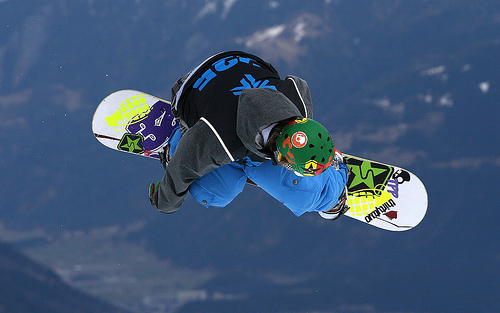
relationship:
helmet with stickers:
[269, 115, 340, 179] [303, 145, 304, 146]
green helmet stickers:
[316, 162, 318, 164] [303, 145, 304, 146]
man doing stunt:
[251, 121, 252, 122] [256, 117, 257, 118]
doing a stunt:
[223, 148, 224, 151] [256, 117, 257, 118]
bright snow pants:
[220, 184, 221, 185] [202, 185, 332, 204]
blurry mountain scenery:
[52, 22, 150, 170] [63, 41, 82, 196]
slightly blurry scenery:
[13, 58, 56, 302] [63, 41, 82, 196]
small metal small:
[198, 198, 210, 212] [201, 199, 209, 206]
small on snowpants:
[201, 199, 209, 206] [164, 182, 238, 229]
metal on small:
[269, 179, 326, 194] [201, 199, 209, 206]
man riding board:
[251, 121, 252, 122] [92, 117, 458, 218]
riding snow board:
[179, 109, 288, 312] [92, 117, 458, 218]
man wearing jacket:
[251, 121, 252, 122] [139, 89, 375, 227]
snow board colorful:
[349, 148, 443, 247] [361, 114, 424, 294]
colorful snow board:
[361, 114, 424, 294] [92, 117, 458, 218]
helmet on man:
[269, 115, 340, 179] [144, 46, 356, 223]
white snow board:
[28, 90, 240, 173] [92, 117, 458, 218]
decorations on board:
[78, 123, 168, 145] [92, 117, 458, 218]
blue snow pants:
[259, 180, 292, 198] [202, 185, 332, 204]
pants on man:
[202, 185, 332, 204] [144, 46, 356, 223]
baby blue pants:
[232, 154, 321, 213] [202, 185, 332, 204]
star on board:
[107, 130, 142, 158] [92, 117, 458, 218]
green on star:
[316, 162, 318, 164] [107, 130, 142, 158]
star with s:
[107, 130, 142, 158] [357, 153, 377, 187]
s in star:
[357, 153, 377, 187] [107, 130, 142, 158]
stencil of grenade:
[341, 188, 398, 206] [335, 177, 396, 225]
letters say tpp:
[375, 172, 415, 201] [369, 169, 415, 204]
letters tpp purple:
[375, 172, 415, 201] [387, 168, 399, 212]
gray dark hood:
[230, 91, 295, 138] [198, 74, 301, 156]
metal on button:
[292, 179, 299, 185] [277, 177, 315, 198]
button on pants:
[277, 177, 315, 198] [202, 185, 332, 204]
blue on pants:
[259, 180, 292, 198] [202, 185, 332, 204]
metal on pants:
[292, 179, 299, 185] [202, 185, 332, 204]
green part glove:
[316, 162, 318, 164] [130, 170, 174, 220]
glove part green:
[130, 170, 174, 220] [316, 162, 318, 164]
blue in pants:
[259, 180, 292, 198] [202, 185, 332, 204]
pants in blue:
[202, 185, 332, 204] [259, 180, 292, 198]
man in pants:
[144, 46, 356, 223] [202, 185, 332, 204]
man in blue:
[144, 46, 356, 223] [259, 180, 292, 198]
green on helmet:
[316, 162, 318, 164] [269, 115, 340, 179]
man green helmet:
[144, 46, 356, 223] [269, 115, 340, 179]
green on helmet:
[316, 162, 318, 164] [249, 113, 356, 193]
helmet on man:
[249, 113, 356, 193] [144, 46, 356, 223]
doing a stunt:
[223, 148, 224, 151] [141, 47, 355, 223]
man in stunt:
[144, 46, 356, 223] [141, 47, 355, 223]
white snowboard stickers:
[28, 90, 240, 173] [303, 145, 304, 146]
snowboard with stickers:
[92, 117, 458, 218] [303, 145, 304, 146]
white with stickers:
[28, 90, 240, 173] [84, 50, 181, 185]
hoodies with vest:
[157, 73, 296, 224] [150, 65, 287, 156]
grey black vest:
[182, 83, 279, 147] [150, 65, 287, 156]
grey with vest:
[182, 83, 279, 147] [150, 65, 287, 156]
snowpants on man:
[164, 182, 238, 229] [144, 46, 356, 223]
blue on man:
[259, 180, 292, 198] [144, 46, 356, 223]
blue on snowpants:
[259, 180, 292, 198] [164, 182, 238, 229]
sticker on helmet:
[275, 133, 324, 150] [269, 115, 340, 179]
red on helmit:
[268, 136, 319, 147] [281, 129, 312, 158]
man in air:
[144, 46, 356, 223] [116, 71, 344, 311]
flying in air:
[121, 150, 162, 161] [116, 71, 344, 311]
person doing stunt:
[116, 71, 344, 311] [141, 47, 355, 223]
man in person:
[144, 46, 356, 223] [116, 71, 344, 311]